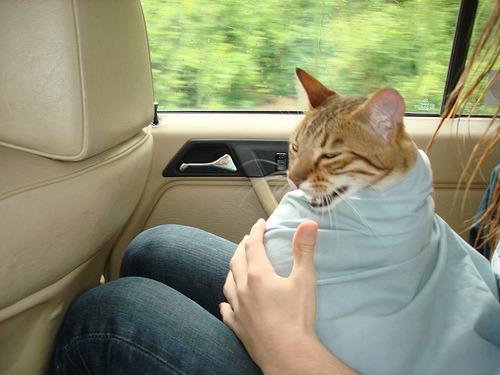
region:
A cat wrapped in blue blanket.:
[268, 58, 494, 358]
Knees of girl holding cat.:
[73, 222, 227, 371]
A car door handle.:
[220, 147, 277, 209]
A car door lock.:
[151, 98, 166, 125]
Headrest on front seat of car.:
[0, 3, 156, 170]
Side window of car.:
[161, 11, 468, 111]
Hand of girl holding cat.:
[222, 211, 322, 361]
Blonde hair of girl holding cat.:
[426, 21, 499, 243]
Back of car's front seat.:
[8, 153, 155, 315]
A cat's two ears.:
[292, 61, 409, 137]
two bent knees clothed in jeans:
[58, 205, 208, 360]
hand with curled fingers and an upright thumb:
[215, 206, 345, 346]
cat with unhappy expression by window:
[282, 57, 412, 207]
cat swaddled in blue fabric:
[260, 76, 480, 347]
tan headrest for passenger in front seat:
[30, 15, 165, 170]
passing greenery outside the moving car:
[175, 10, 415, 90]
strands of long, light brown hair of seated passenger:
[410, 25, 490, 250]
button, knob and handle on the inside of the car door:
[146, 92, 271, 192]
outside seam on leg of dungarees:
[25, 315, 225, 370]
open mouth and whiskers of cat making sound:
[280, 170, 396, 220]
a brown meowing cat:
[275, 63, 415, 218]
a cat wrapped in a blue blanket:
[235, 55, 490, 370]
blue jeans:
[55, 211, 255, 367]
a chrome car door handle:
[170, 140, 240, 175]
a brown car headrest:
[0, 2, 157, 164]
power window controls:
[266, 145, 286, 176]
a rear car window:
[150, 0, 495, 117]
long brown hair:
[425, 1, 495, 246]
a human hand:
[210, 212, 365, 372]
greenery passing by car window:
[153, 2, 441, 111]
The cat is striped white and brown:
[287, 59, 414, 221]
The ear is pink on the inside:
[360, 88, 405, 150]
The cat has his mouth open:
[285, 166, 353, 221]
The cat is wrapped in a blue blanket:
[260, 143, 475, 365]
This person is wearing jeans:
[95, 218, 246, 368]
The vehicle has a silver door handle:
[168, 140, 259, 185]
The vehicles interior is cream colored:
[10, 4, 155, 366]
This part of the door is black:
[162, 126, 352, 193]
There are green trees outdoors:
[171, 6, 435, 101]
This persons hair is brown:
[426, 5, 497, 226]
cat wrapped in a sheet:
[264, 73, 469, 373]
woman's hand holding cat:
[218, 208, 359, 373]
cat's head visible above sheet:
[262, 59, 415, 214]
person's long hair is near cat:
[378, 4, 498, 244]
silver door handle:
[175, 145, 238, 184]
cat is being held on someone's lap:
[146, 228, 307, 352]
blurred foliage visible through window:
[145, 0, 472, 112]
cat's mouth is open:
[288, 180, 345, 207]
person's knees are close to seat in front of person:
[50, 217, 140, 356]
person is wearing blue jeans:
[75, 303, 189, 349]